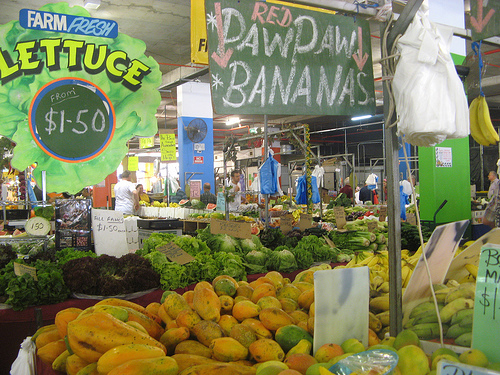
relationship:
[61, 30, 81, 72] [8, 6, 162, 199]
letter on a sign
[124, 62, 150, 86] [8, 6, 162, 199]
letter on a sign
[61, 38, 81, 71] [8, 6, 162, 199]
letter on a sign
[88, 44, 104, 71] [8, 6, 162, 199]
letter on a sign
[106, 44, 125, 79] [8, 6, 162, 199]
letter on a sign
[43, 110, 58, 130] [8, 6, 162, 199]
dollar sign on a sign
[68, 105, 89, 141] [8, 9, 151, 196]
number on a sign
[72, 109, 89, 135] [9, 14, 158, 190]
number on a sign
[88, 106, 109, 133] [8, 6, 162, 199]
number on a sign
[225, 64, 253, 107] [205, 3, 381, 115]
letter on a sign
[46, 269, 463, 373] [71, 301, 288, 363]
bin of squash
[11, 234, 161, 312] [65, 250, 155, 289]
bin of lettuce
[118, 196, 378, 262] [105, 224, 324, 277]
table of greens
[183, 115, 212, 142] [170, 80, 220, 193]
fan attached sign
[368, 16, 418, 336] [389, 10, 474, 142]
pole with bags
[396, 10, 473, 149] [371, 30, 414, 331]
bags hanging poles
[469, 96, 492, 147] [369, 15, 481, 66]
banana on stand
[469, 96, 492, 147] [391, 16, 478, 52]
banana on stand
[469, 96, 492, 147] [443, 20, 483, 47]
banana on stand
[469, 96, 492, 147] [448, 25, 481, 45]
banana on stand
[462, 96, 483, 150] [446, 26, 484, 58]
banana on stand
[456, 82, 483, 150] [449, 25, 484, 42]
banana on stand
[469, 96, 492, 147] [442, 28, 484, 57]
banana on stand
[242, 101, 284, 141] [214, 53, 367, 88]
white writing on sign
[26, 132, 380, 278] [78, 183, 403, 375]
people standing in market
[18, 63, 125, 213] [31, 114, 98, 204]
sign shaped like a lettuce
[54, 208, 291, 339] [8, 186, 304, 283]
different types of lettuce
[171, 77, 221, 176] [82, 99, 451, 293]
pillar in background